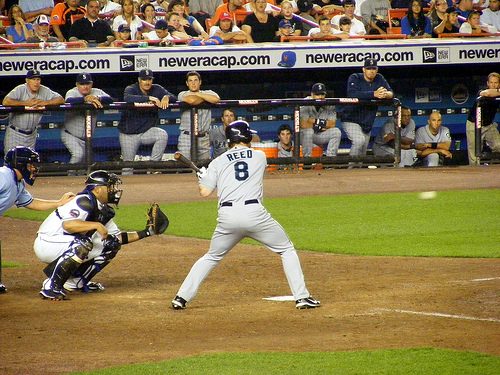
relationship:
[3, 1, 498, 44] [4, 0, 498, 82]
fans on stands